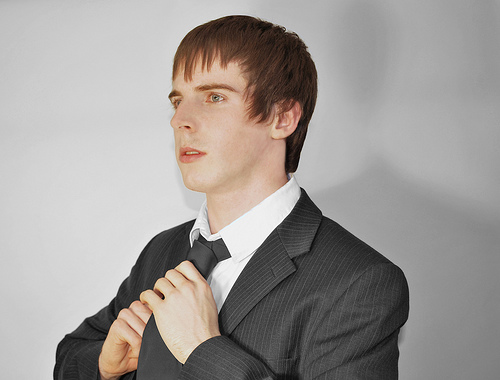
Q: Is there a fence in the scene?
A: No, there are no fences.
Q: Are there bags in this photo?
A: No, there are no bags.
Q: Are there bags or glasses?
A: No, there are no bags or glasses.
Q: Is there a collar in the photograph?
A: Yes, there is a collar.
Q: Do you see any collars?
A: Yes, there is a collar.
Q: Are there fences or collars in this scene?
A: Yes, there is a collar.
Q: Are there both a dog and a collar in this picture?
A: No, there is a collar but no dogs.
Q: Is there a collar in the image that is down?
A: Yes, there is a collar that is down.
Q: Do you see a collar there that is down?
A: Yes, there is a collar that is down.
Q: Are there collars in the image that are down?
A: Yes, there is a collar that is down.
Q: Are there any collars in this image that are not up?
A: Yes, there is a collar that is down.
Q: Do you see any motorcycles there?
A: No, there are no motorcycles.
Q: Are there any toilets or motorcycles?
A: No, there are no motorcycles or toilets.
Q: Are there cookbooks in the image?
A: No, there are no cookbooks.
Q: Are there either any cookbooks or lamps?
A: No, there are no cookbooks or lamps.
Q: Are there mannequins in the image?
A: No, there are no mannequins.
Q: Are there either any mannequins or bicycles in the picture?
A: No, there are no mannequins or bicycles.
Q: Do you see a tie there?
A: Yes, there is a tie.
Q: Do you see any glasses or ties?
A: Yes, there is a tie.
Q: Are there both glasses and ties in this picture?
A: No, there is a tie but no glasses.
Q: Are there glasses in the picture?
A: No, there are no glasses.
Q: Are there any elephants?
A: No, there are no elephants.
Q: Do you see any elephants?
A: No, there are no elephants.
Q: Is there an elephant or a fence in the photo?
A: No, there are no elephants or fences.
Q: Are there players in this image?
A: No, there are no players.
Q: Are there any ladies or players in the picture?
A: No, there are no players or ladies.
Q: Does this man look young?
A: Yes, the man is young.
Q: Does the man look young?
A: Yes, the man is young.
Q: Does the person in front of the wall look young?
A: Yes, the man is young.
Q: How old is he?
A: The man is young.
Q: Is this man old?
A: No, the man is young.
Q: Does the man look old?
A: No, the man is young.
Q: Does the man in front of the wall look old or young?
A: The man is young.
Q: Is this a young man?
A: Yes, this is a young man.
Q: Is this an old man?
A: No, this is a young man.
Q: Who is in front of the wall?
A: The man is in front of the wall.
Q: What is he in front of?
A: The man is in front of the wall.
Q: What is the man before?
A: The man is in front of the wall.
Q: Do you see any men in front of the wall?
A: Yes, there is a man in front of the wall.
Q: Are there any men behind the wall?
A: No, the man is in front of the wall.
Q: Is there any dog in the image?
A: No, there are no dogs.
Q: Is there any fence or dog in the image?
A: No, there are no dogs or fences.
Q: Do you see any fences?
A: No, there are no fences.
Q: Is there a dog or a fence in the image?
A: No, there are no fences or dogs.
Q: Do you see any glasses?
A: No, there are no glasses.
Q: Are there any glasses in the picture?
A: No, there are no glasses.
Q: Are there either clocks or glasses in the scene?
A: No, there are no glasses or clocks.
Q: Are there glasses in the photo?
A: No, there are no glasses.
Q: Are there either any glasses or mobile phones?
A: No, there are no glasses or mobile phones.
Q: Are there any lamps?
A: No, there are no lamps.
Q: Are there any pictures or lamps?
A: No, there are no lamps or pictures.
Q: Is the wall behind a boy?
A: No, the wall is behind the man.